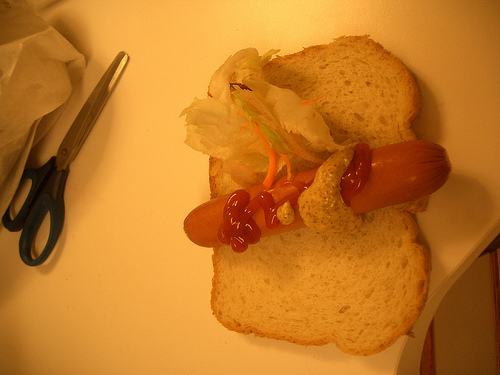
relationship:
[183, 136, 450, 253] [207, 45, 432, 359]
hot dog laying on bread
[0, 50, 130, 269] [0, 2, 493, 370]
scissors sitting on top counter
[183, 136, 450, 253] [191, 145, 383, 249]
hot dog smothered in condiments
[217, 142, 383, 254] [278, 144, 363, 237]
condiments mixed with mustard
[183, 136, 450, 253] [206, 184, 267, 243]
hot dog with ketchup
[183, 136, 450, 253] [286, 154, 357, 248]
hot dog with mustard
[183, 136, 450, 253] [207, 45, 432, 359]
hot dog on bread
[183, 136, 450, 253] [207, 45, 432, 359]
hot dog on slice bread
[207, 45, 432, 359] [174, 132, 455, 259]
bread with sausage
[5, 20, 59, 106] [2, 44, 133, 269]
napkin near scissors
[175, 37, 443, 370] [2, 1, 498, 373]
sandwich in white table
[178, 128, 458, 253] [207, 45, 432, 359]
hot dog on bread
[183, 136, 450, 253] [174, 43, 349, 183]
hot dog with lettuce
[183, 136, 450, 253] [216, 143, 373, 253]
hot dog with ketchup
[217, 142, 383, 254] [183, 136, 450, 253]
condiments on hot dog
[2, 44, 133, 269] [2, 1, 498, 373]
scissors on white table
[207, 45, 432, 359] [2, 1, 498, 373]
bread on white table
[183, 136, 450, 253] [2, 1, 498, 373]
hot dog on white table